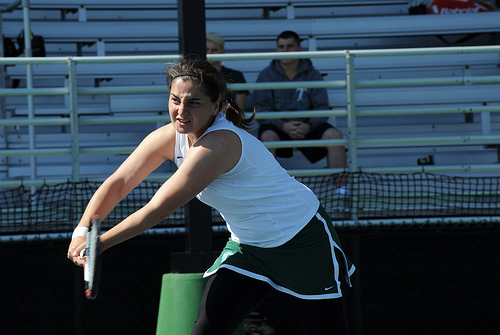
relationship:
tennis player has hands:
[69, 57, 356, 334] [68, 229, 99, 264]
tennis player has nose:
[69, 57, 356, 334] [178, 97, 191, 117]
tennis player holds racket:
[69, 57, 356, 334] [80, 217, 99, 299]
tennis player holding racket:
[69, 57, 356, 334] [80, 217, 99, 299]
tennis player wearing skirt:
[69, 57, 356, 334] [202, 209, 358, 301]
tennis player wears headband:
[69, 57, 356, 334] [172, 71, 199, 76]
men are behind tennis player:
[208, 31, 355, 203] [69, 57, 356, 334]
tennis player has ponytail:
[69, 57, 356, 334] [227, 99, 256, 129]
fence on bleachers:
[0, 46, 499, 243] [0, 3, 483, 196]